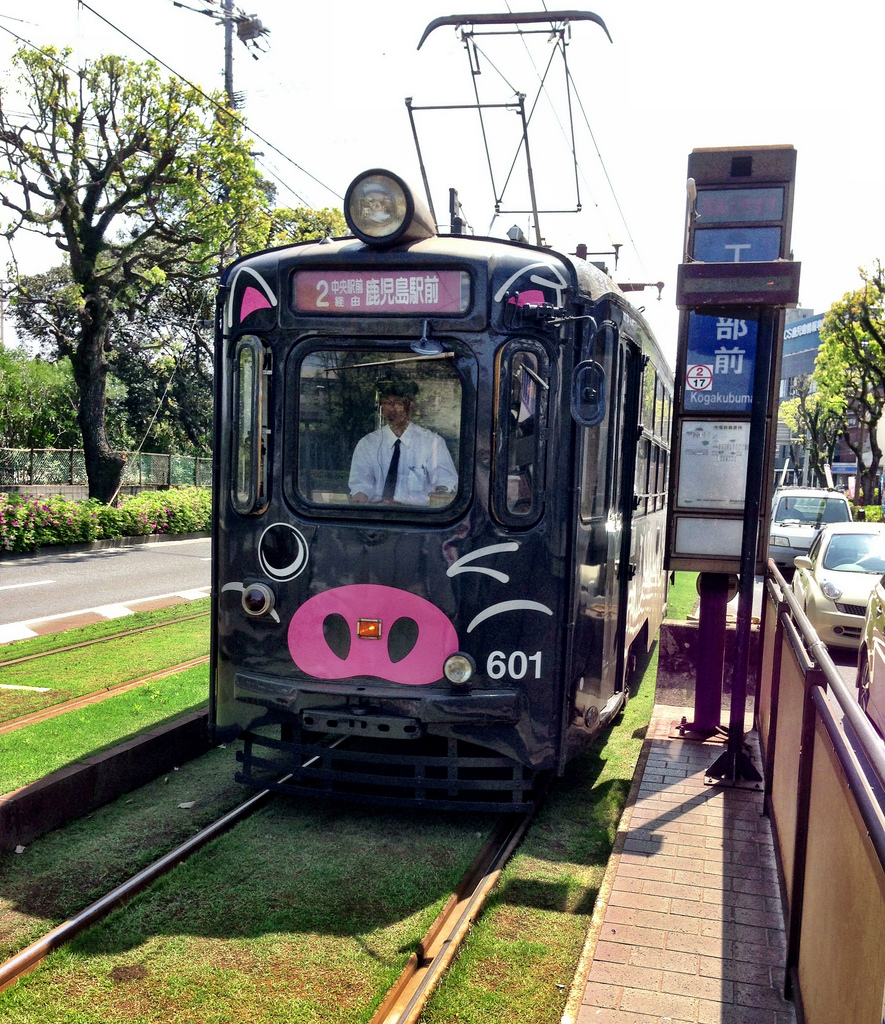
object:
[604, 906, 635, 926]
brick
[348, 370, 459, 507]
driving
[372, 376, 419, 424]
head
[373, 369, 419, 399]
hat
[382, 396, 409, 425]
face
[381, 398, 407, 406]
glassses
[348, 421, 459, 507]
shirt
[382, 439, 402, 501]
tie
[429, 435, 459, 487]
arm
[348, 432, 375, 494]
arm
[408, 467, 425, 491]
pocket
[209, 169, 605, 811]
front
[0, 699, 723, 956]
shadow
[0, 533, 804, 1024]
ground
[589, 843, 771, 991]
bricks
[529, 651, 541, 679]
number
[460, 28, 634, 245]
wires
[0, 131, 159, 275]
branches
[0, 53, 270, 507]
tree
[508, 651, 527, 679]
number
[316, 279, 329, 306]
number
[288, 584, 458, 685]
logo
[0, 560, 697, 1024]
grass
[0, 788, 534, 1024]
tracks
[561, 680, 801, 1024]
platform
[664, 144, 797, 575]
sign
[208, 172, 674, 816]
train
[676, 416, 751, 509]
sign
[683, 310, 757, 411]
sign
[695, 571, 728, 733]
pole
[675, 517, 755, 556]
sign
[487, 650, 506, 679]
number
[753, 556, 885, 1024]
fence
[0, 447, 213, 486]
fence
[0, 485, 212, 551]
flowers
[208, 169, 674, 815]
train car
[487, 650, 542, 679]
numbers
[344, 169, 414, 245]
light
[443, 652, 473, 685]
light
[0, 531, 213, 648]
road